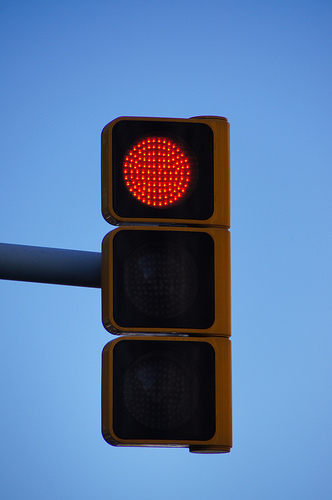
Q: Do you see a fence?
A: No, there are no fences.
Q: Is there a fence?
A: No, there are no fences.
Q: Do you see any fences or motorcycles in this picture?
A: No, there are no fences or motorcycles.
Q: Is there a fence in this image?
A: No, there are no fences.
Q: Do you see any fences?
A: No, there are no fences.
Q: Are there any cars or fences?
A: No, there are no fences or cars.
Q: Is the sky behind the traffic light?
A: Yes, the sky is behind the traffic light.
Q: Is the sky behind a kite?
A: No, the sky is behind the traffic light.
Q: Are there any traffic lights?
A: Yes, there is a traffic light.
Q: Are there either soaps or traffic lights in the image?
A: Yes, there is a traffic light.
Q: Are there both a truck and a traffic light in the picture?
A: No, there is a traffic light but no trucks.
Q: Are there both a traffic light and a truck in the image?
A: No, there is a traffic light but no trucks.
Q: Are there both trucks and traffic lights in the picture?
A: No, there is a traffic light but no trucks.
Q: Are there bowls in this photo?
A: No, there are no bowls.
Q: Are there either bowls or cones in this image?
A: No, there are no bowls or cones.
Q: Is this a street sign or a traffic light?
A: This is a traffic light.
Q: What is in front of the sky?
A: The traffic light is in front of the sky.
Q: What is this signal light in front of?
A: The signal light is in front of the sky.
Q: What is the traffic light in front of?
A: The signal light is in front of the sky.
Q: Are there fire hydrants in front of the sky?
A: No, there is a traffic light in front of the sky.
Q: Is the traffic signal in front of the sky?
A: Yes, the traffic signal is in front of the sky.